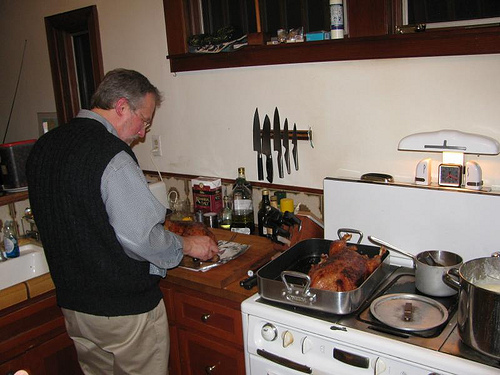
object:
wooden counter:
[0, 222, 284, 317]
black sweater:
[26, 117, 164, 317]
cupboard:
[165, 287, 243, 375]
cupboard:
[0, 287, 68, 375]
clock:
[437, 163, 462, 187]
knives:
[253, 106, 315, 183]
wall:
[0, 0, 500, 195]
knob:
[201, 314, 208, 321]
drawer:
[173, 289, 242, 344]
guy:
[23, 68, 218, 375]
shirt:
[73, 107, 186, 279]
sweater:
[24, 117, 166, 316]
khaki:
[55, 300, 168, 375]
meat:
[163, 219, 220, 268]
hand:
[182, 235, 219, 262]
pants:
[61, 299, 173, 375]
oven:
[239, 259, 499, 375]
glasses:
[117, 93, 152, 133]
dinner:
[164, 219, 221, 267]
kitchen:
[0, 0, 500, 375]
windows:
[178, 0, 330, 35]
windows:
[401, 0, 500, 30]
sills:
[165, 27, 500, 73]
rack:
[260, 127, 315, 149]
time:
[441, 167, 458, 183]